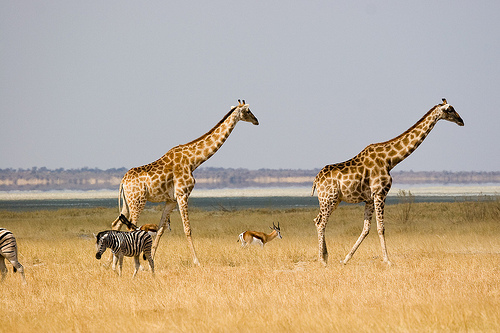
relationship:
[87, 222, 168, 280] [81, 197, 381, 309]
zebra in a field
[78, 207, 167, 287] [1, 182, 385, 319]
zebra in a field